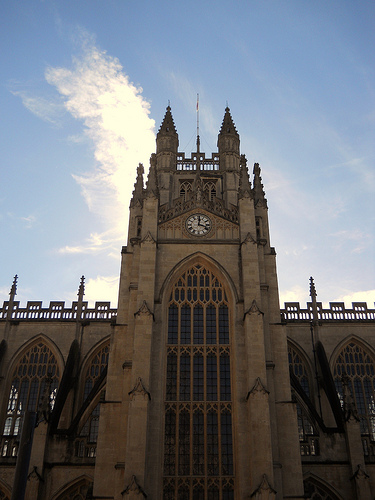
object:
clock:
[185, 209, 216, 239]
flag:
[195, 93, 200, 112]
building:
[0, 88, 374, 499]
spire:
[309, 273, 317, 298]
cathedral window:
[161, 248, 238, 497]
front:
[1, 90, 374, 500]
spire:
[194, 92, 202, 149]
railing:
[0, 299, 120, 321]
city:
[1, 0, 374, 500]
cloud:
[42, 31, 165, 315]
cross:
[80, 273, 88, 281]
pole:
[75, 274, 85, 322]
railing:
[47, 340, 77, 454]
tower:
[114, 93, 282, 322]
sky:
[0, 1, 375, 319]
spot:
[248, 266, 255, 276]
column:
[236, 152, 275, 499]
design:
[0, 96, 374, 493]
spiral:
[216, 100, 240, 140]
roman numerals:
[206, 223, 210, 227]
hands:
[198, 215, 201, 227]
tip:
[167, 97, 175, 107]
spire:
[156, 99, 179, 142]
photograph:
[5, 4, 374, 499]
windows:
[164, 298, 180, 348]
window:
[178, 179, 193, 198]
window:
[201, 179, 221, 202]